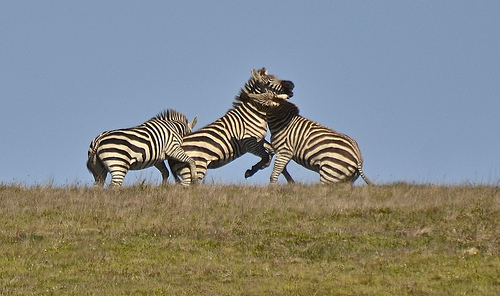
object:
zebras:
[86, 106, 198, 191]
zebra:
[243, 91, 377, 191]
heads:
[245, 67, 294, 92]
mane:
[275, 90, 301, 114]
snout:
[238, 92, 266, 107]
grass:
[0, 178, 499, 295]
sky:
[0, 0, 499, 187]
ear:
[249, 68, 261, 82]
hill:
[0, 183, 500, 295]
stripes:
[320, 163, 351, 177]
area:
[0, 180, 499, 295]